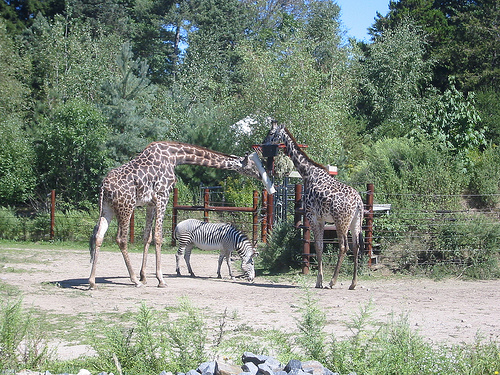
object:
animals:
[87, 121, 365, 290]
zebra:
[170, 217, 260, 281]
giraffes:
[257, 119, 364, 290]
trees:
[10, 10, 478, 135]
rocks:
[154, 351, 326, 373]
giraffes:
[87, 140, 265, 291]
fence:
[51, 194, 468, 264]